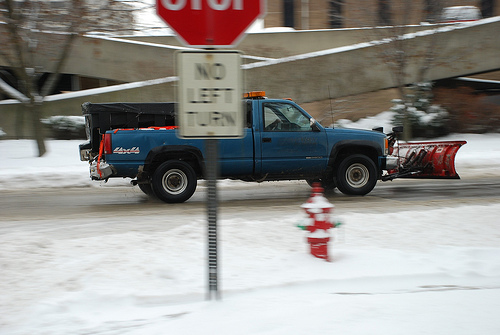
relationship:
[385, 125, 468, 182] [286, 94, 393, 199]
plow in front of truck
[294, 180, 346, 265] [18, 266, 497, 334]
hydrant near sidewalk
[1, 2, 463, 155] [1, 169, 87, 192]
trees grow near far sidewalk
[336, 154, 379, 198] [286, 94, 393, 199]
tire on right front of truck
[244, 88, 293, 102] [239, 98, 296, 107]
orange lights on truck roof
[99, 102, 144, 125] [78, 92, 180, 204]
black straps on back of truck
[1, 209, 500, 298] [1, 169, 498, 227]
packed snow along street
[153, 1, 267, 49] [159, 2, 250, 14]
sign says stop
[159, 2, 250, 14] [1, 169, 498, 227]
stop at street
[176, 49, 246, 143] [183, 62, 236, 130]
traffic sign says no left turn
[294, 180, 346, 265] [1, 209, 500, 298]
hydrant near packed snow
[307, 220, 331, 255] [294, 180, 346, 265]
red color of hydrant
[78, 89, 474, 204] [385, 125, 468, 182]
truck has a plow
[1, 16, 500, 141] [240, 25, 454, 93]
ramps made of cement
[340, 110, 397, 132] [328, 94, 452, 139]
snow tops bushes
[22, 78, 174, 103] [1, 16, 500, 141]
snow accumulated on ramps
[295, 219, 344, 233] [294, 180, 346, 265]
green plugs on hydrant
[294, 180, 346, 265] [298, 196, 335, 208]
hydrant covered in snow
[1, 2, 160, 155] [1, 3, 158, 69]
tree has no leaves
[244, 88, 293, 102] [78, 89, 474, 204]
orange lights on truck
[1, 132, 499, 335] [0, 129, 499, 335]
snow on ground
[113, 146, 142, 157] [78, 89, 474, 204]
4x4 on truck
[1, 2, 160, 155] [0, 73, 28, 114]
tree has snow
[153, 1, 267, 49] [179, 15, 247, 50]
sign painted in red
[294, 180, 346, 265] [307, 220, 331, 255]
hydrant painted red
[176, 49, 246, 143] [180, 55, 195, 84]
traffic sign background white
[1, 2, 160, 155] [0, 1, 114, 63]
tree has brown leaves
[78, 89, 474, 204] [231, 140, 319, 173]
truck painted blue